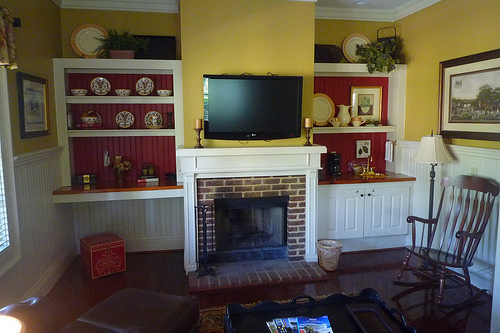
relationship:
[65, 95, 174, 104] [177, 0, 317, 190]
shelf on wall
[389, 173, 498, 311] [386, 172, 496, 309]
rocking chair against wall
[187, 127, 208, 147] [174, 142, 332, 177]
candle stick on fireplace mantle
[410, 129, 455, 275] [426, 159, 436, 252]
floor lamp sitting on base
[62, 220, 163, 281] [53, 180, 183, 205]
gold box sitting under shelf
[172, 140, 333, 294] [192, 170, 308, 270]
mantlepiece surrounding fireplace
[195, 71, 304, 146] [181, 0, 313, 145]
television mounted on wall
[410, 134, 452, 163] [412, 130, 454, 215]
white shade sitting on top of floor lamp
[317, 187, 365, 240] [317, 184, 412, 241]
door leading to cabinet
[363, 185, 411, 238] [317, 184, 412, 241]
door leading to cabinet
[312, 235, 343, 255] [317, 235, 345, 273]
liner sitting in waste basket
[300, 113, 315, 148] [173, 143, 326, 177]
candle sitting on mantlepiece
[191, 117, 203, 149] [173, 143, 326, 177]
candle sitting on mantlepiece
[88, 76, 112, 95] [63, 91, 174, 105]
display plate sitting on shelf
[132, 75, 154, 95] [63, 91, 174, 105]
display plate sitting on shelf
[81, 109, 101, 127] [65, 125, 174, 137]
display plate sitting on shelf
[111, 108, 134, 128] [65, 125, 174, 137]
display plate sitting on shelf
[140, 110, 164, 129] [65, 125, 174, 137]
display plate sitting on shelf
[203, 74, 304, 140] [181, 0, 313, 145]
television mounted on wall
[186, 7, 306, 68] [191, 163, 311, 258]
yellow wall standing above fire place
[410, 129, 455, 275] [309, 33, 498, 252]
floor lamp standing in front of wall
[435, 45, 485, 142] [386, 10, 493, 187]
painting hanging on wall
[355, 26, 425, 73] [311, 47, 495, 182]
basket sitting on shelf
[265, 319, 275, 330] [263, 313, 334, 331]
magazine lying in group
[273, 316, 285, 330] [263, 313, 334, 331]
magazine lying in group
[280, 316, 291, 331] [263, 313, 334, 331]
magazine lying in group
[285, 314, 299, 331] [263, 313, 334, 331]
magazine lying in group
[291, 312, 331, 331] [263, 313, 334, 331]
magazine lying in group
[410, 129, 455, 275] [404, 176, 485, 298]
floor lamp standing next chair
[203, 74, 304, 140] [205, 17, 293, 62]
television on wall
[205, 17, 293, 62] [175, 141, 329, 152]
wall over mantle